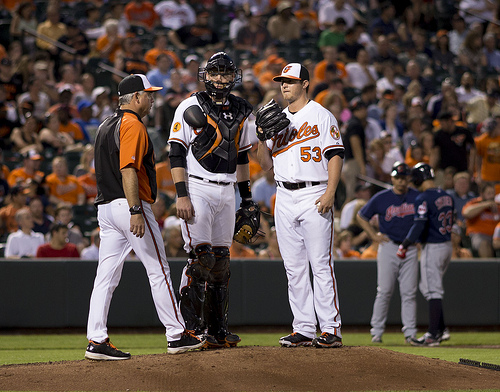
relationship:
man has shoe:
[85, 73, 207, 361] [84, 338, 131, 361]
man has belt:
[255, 62, 346, 350] [276, 181, 320, 190]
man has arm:
[85, 73, 207, 361] [118, 121, 146, 238]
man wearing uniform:
[356, 161, 418, 343] [358, 190, 419, 338]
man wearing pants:
[356, 161, 418, 343] [370, 242, 419, 338]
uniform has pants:
[358, 190, 419, 338] [370, 242, 419, 338]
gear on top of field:
[167, 51, 261, 348] [1, 329, 499, 390]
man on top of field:
[85, 73, 207, 361] [1, 329, 499, 390]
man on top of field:
[255, 62, 346, 350] [1, 329, 499, 390]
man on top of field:
[356, 161, 418, 343] [1, 329, 499, 390]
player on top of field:
[396, 162, 455, 347] [1, 329, 499, 390]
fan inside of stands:
[4, 209, 44, 258] [0, 1, 499, 260]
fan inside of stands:
[9, 114, 43, 154] [0, 1, 499, 260]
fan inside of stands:
[461, 182, 499, 257] [0, 1, 499, 260]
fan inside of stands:
[341, 97, 369, 201] [0, 1, 499, 260]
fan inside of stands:
[37, 222, 80, 258] [0, 1, 499, 260]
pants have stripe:
[274, 180, 342, 340] [328, 212, 341, 337]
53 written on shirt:
[300, 145, 322, 163] [265, 99, 345, 183]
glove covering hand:
[255, 99, 291, 142] [314, 193, 336, 216]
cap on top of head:
[273, 61, 310, 81] [272, 63, 309, 103]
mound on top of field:
[2, 346, 499, 392] [1, 329, 499, 390]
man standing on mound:
[255, 62, 346, 350] [2, 346, 499, 392]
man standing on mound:
[85, 73, 207, 361] [2, 346, 499, 392]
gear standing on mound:
[167, 51, 261, 348] [2, 346, 499, 392]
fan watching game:
[9, 114, 43, 154] [1, 51, 499, 390]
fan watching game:
[4, 209, 44, 258] [1, 51, 499, 390]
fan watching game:
[37, 222, 80, 258] [1, 51, 499, 390]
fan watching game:
[461, 182, 499, 257] [1, 51, 499, 390]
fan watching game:
[341, 97, 369, 201] [1, 51, 499, 390]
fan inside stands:
[9, 114, 43, 154] [0, 1, 499, 260]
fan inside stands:
[4, 209, 44, 258] [0, 1, 499, 260]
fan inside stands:
[37, 222, 80, 258] [0, 1, 499, 260]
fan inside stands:
[341, 97, 369, 201] [0, 1, 499, 260]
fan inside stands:
[461, 182, 499, 257] [0, 1, 499, 260]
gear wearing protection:
[167, 51, 261, 348] [180, 242, 215, 330]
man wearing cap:
[255, 62, 346, 350] [273, 61, 310, 81]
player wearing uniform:
[396, 162, 455, 347] [396, 188, 456, 348]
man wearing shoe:
[85, 73, 207, 361] [84, 338, 131, 361]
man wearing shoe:
[85, 73, 207, 361] [166, 331, 206, 354]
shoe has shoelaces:
[84, 338, 131, 361] [107, 341, 118, 350]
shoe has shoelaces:
[166, 331, 206, 354] [185, 328, 203, 344]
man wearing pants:
[255, 62, 346, 350] [274, 180, 342, 340]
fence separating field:
[0, 259, 499, 327] [1, 329, 499, 390]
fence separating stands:
[0, 259, 499, 327] [0, 1, 499, 260]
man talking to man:
[85, 73, 207, 361] [255, 62, 346, 350]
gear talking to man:
[167, 51, 261, 348] [85, 73, 207, 361]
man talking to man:
[255, 62, 346, 350] [85, 73, 207, 361]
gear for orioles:
[167, 51, 261, 348] [269, 121, 321, 157]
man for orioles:
[255, 62, 346, 350] [269, 121, 321, 157]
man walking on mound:
[85, 73, 207, 361] [2, 346, 499, 392]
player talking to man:
[396, 162, 455, 347] [356, 161, 418, 343]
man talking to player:
[356, 161, 418, 343] [396, 162, 455, 347]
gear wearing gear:
[167, 51, 261, 348] [184, 51, 253, 347]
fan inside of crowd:
[4, 209, 44, 258] [2, 1, 499, 258]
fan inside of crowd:
[37, 222, 80, 258] [2, 1, 499, 258]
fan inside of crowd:
[9, 114, 43, 154] [2, 1, 499, 258]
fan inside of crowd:
[461, 182, 499, 257] [2, 1, 499, 258]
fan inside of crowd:
[341, 97, 369, 201] [2, 1, 499, 258]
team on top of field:
[85, 51, 344, 361] [1, 329, 499, 390]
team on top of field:
[356, 161, 455, 347] [1, 329, 499, 390]